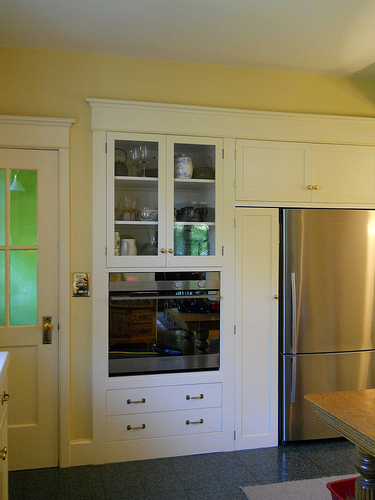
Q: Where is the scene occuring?
A: Kitchen.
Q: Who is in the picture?
A: No one.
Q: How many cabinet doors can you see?
A: 5.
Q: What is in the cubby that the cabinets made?
A: Refrigerator.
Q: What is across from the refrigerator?
A: An Island.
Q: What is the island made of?
A: Wood.